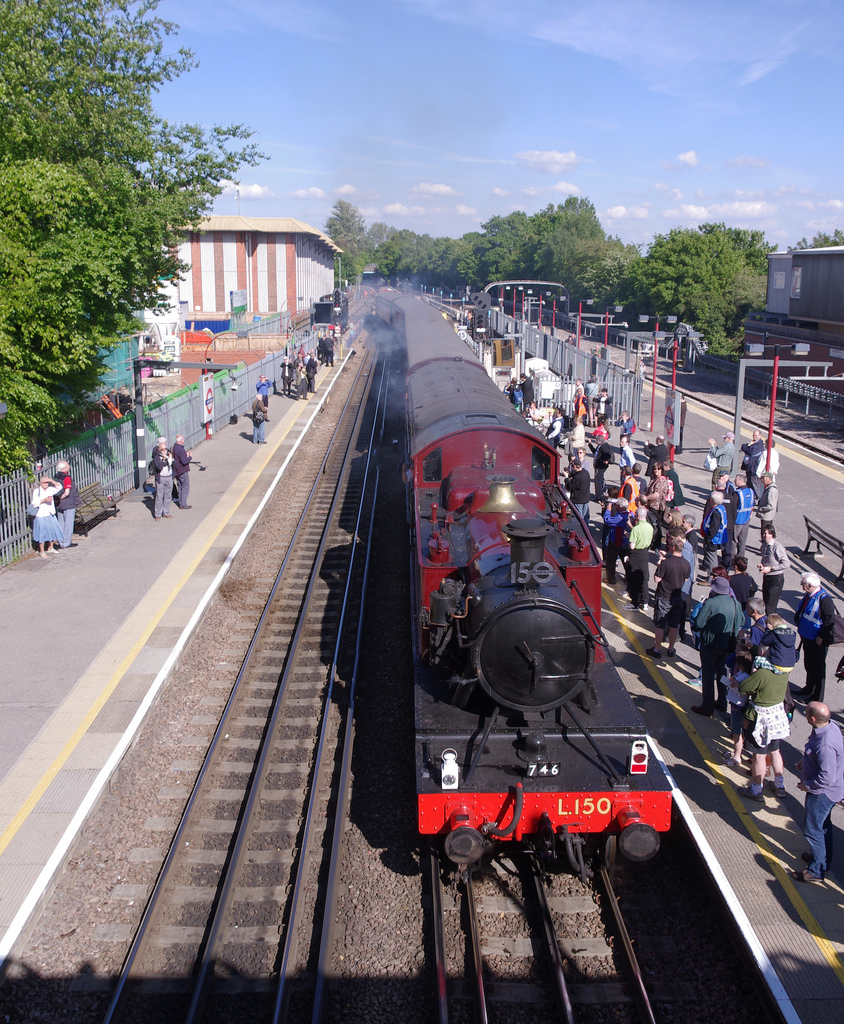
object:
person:
[625, 502, 652, 607]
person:
[648, 462, 672, 516]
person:
[682, 512, 698, 544]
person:
[729, 473, 758, 546]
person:
[757, 436, 780, 474]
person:
[751, 526, 787, 614]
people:
[797, 565, 832, 710]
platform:
[676, 392, 830, 837]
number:
[574, 799, 614, 823]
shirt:
[803, 736, 844, 804]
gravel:
[351, 856, 421, 1000]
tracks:
[522, 928, 652, 971]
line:
[6, 435, 274, 976]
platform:
[6, 547, 149, 723]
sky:
[44, 2, 841, 252]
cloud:
[667, 91, 709, 144]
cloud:
[447, 147, 517, 175]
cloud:
[662, 195, 768, 225]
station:
[4, 217, 842, 1020]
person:
[168, 432, 203, 517]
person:
[257, 375, 272, 398]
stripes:
[285, 235, 296, 323]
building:
[142, 214, 346, 316]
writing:
[557, 798, 614, 817]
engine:
[401, 413, 668, 862]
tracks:
[322, 616, 366, 1003]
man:
[789, 698, 840, 882]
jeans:
[802, 791, 831, 876]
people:
[757, 523, 789, 612]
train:
[371, 282, 674, 877]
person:
[735, 667, 799, 793]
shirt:
[741, 663, 786, 707]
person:
[751, 471, 783, 540]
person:
[590, 432, 610, 500]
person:
[595, 384, 614, 418]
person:
[145, 438, 181, 517]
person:
[51, 458, 83, 549]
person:
[687, 575, 745, 717]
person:
[653, 537, 689, 658]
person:
[26, 473, 58, 552]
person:
[243, 391, 269, 443]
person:
[751, 610, 796, 678]